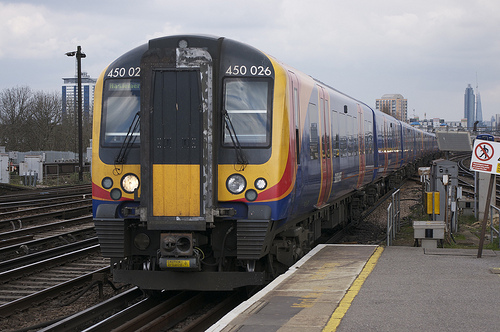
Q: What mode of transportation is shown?
A: Train.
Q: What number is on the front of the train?
A: 450 026.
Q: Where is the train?
A: Tracks.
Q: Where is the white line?
A: On the concrete.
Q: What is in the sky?
A: Clouds.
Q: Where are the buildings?
A: Background on the right side.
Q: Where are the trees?
A: Background on the left side.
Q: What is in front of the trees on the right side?
A: Building.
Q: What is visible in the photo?
A: A train.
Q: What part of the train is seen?
A: The yellow front.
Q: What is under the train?
A: A set of train tracks.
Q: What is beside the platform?
A: A blue, yellow and red train.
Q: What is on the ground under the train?
A: Several train tracks.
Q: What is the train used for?
A: Transportation.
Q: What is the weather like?
A: It is a cloudy day.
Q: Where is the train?
A: On the tracks.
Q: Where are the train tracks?
A: On the ground.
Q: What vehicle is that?
A: A train.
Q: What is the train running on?
A: Tracks.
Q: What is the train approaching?
A: Platform.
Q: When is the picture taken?
A: Daytime.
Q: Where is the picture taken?
A: Train station.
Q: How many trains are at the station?
A: One.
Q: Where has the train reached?
A: Edge of platform.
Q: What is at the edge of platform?
A: Caution sign.